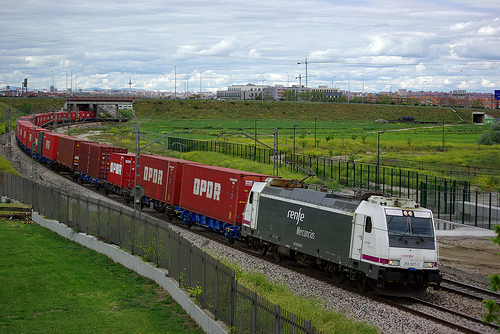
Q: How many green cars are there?
A: One.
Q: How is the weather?
A: Cloudy.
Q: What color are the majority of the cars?
A: Red.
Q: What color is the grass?
A: Green.